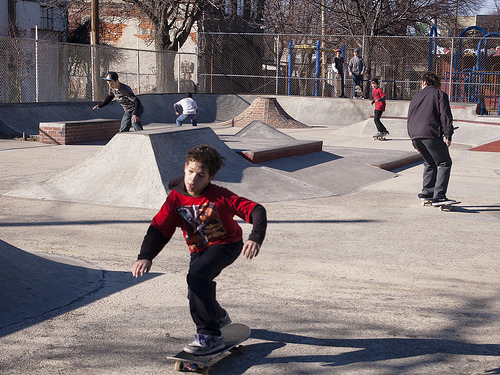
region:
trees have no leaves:
[263, 0, 481, 75]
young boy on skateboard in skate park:
[129, 142, 278, 361]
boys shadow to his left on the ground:
[119, 149, 479, 366]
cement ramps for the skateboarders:
[224, 100, 378, 235]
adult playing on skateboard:
[391, 57, 466, 232]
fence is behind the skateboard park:
[179, 23, 489, 110]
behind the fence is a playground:
[281, 27, 494, 109]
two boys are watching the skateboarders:
[321, 40, 369, 99]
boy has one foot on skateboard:
[155, 308, 255, 366]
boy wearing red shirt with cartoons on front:
[131, 182, 278, 267]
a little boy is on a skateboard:
[114, 140, 286, 372]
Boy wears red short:
[123, 129, 283, 371]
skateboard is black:
[157, 317, 266, 374]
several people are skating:
[67, 35, 479, 368]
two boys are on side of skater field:
[321, 45, 368, 98]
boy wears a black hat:
[83, 68, 151, 136]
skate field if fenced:
[7, 30, 499, 372]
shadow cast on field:
[256, 312, 482, 374]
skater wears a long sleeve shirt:
[392, 60, 465, 217]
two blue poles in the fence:
[273, 24, 330, 101]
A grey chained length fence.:
[7, 33, 498, 110]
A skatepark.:
[11, 49, 498, 373]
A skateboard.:
[142, 317, 257, 372]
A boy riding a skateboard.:
[126, 136, 270, 373]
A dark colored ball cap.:
[99, 68, 121, 83]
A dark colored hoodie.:
[406, 83, 456, 144]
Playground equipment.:
[263, 20, 496, 120]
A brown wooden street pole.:
[85, 1, 108, 108]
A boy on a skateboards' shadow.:
[249, 318, 496, 374]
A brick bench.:
[36, 114, 123, 144]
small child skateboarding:
[139, 150, 286, 374]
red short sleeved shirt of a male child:
[139, 176, 299, 267]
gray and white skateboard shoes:
[169, 321, 257, 363]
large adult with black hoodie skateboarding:
[397, 42, 461, 239]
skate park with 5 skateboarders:
[28, 48, 475, 297]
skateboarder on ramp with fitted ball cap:
[87, 56, 176, 163]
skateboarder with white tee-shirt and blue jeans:
[166, 91, 211, 135]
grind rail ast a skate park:
[21, 112, 69, 155]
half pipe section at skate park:
[222, 84, 357, 186]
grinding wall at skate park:
[32, 98, 128, 140]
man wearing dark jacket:
[404, 65, 461, 215]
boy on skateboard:
[128, 143, 277, 372]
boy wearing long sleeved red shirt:
[134, 130, 278, 374]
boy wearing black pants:
[126, 143, 268, 353]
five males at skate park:
[13, 25, 482, 366]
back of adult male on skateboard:
[394, 65, 467, 214]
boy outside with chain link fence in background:
[27, 36, 149, 133]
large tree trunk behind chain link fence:
[126, 5, 194, 95]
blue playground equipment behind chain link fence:
[444, 22, 499, 105]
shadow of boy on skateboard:
[128, 255, 492, 372]